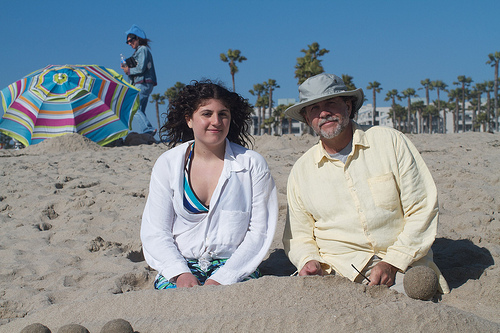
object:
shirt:
[285, 121, 439, 281]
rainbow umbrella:
[0, 62, 145, 149]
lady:
[119, 23, 158, 136]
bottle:
[119, 53, 130, 67]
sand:
[0, 130, 500, 333]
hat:
[124, 23, 147, 41]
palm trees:
[215, 39, 499, 136]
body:
[288, 118, 441, 286]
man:
[281, 72, 449, 296]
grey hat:
[284, 72, 365, 124]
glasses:
[350, 264, 370, 284]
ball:
[402, 265, 437, 301]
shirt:
[128, 44, 159, 85]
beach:
[0, 130, 500, 333]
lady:
[137, 76, 278, 290]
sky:
[0, 0, 499, 110]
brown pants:
[291, 257, 451, 298]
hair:
[158, 78, 256, 149]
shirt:
[140, 137, 277, 286]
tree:
[292, 40, 332, 136]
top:
[183, 142, 210, 214]